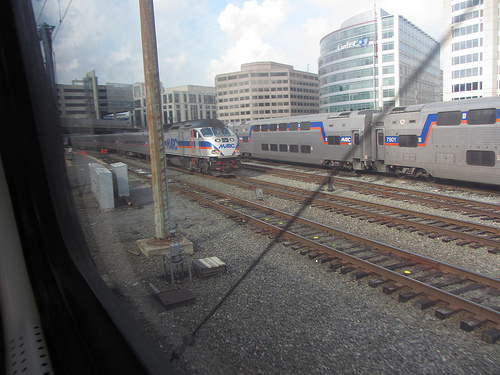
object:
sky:
[25, 0, 446, 92]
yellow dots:
[403, 270, 413, 275]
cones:
[101, 147, 107, 158]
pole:
[137, 0, 171, 243]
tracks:
[76, 145, 500, 343]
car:
[230, 95, 500, 185]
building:
[56, 0, 500, 149]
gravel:
[273, 281, 391, 367]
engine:
[238, 92, 498, 194]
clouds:
[33, 0, 441, 87]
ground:
[416, 180, 454, 240]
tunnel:
[63, 116, 139, 151]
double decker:
[225, 95, 500, 183]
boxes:
[88, 162, 115, 212]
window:
[9, 0, 499, 364]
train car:
[68, 119, 241, 178]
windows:
[300, 145, 310, 154]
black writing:
[215, 138, 235, 143]